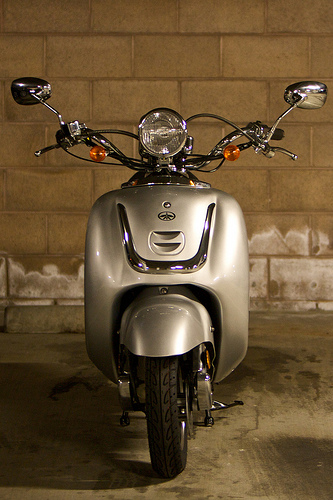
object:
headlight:
[137, 107, 185, 158]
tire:
[139, 355, 191, 481]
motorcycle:
[6, 75, 330, 478]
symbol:
[152, 210, 181, 226]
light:
[221, 143, 242, 162]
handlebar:
[33, 122, 93, 161]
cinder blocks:
[0, 3, 333, 318]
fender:
[115, 294, 215, 361]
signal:
[88, 146, 108, 162]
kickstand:
[199, 393, 250, 424]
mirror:
[282, 79, 329, 112]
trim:
[74, 176, 252, 405]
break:
[212, 117, 296, 168]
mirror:
[10, 73, 53, 109]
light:
[87, 143, 107, 162]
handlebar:
[250, 114, 305, 162]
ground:
[0, 304, 330, 499]